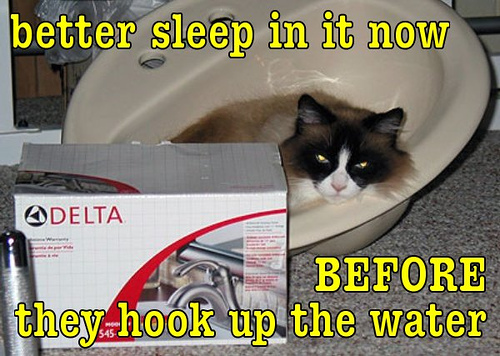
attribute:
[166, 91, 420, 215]
cat — brown, here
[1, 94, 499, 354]
floor — grey, here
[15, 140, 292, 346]
box — white, here, cardboard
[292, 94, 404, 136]
ears — dark, pointy, black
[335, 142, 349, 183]
streak — white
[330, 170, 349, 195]
nose — here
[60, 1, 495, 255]
sink — tan, here, white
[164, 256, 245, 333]
faucet — metal, silver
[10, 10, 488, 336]
writing — here, yellow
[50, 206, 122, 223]
writing — red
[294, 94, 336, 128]
ear — here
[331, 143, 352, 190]
stripe — white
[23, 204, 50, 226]
logo — black, white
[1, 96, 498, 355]
carpet — grey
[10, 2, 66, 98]
wood — brown